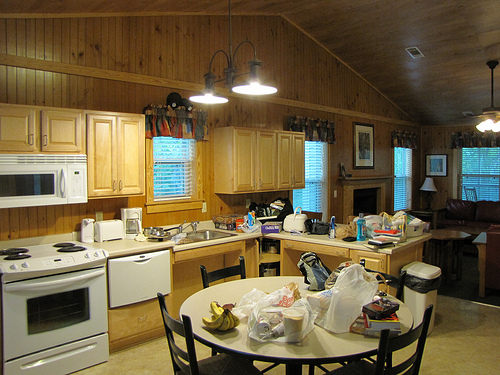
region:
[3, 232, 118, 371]
A WHITE STOVE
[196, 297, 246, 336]
A BUNCH OF BANANAS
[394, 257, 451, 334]
A KITCHEN GARBAGE CAN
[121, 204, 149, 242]
A WHITE COFFEE MAKER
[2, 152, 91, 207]
AN UNDER THE CABINET MICROWAVE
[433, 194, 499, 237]
A BROWN LIVING ROOM SOFA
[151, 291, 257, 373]
A WOODEN KITCHEN CHAIR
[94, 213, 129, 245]
A WHITE TOASTER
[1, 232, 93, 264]
A SET OF FOUR STOVE BURNERS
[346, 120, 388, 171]
A PICTURE HANGING ON THE WALL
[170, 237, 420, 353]
A brown and white kitchen table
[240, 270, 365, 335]
Grocery bags on top of the table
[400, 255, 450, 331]
A white garbage pail with a black trash bag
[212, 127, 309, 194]
Brown wooden cupboards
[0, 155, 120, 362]
A white kitchen stove with a microwave above it.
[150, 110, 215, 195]
A multi colored valance on window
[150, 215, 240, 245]
A stainless steel kitchen sink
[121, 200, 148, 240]
A white coffee pot next to the kitchen sink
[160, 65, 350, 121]
Two light fixtures on the kitchen ceiling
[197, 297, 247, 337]
Bananas on the kitchen table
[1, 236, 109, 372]
a white oven and stovetop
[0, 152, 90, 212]
a white microwave range hood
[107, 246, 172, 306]
a white dishwasher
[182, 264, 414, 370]
a round white kitchen table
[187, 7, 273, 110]
a overhead kitchen light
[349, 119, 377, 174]
a framed photo on wall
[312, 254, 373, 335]
a white plastic bag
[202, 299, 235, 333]
a bunch of bananas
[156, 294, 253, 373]
a black kitchen chair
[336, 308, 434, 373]
a black kitchen chair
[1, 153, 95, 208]
the microwave is white.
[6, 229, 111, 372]
the oven is white.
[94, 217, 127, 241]
toaster on the counter.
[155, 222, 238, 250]
the sink is silver.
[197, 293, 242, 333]
bananas on the table.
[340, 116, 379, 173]
picture on the wall.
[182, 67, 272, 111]
the lights are on.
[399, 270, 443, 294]
black bag in trashcan.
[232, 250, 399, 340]
plastic bags on the table.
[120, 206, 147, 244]
coffee pot on the counter.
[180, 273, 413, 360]
White, round kitchen table top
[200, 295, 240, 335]
Bunch of bananas on kitchen table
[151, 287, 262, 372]
Brown wooden chair at table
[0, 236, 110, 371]
White stove in kitchen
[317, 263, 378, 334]
White plastic bag on table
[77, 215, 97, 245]
White can opener on kitchen counter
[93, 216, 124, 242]
White toaster on kitchen counter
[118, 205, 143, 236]
White coffee maker on kitchen counter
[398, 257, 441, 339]
White trashcan in kitchen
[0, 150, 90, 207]
White microwave oven in kitchen